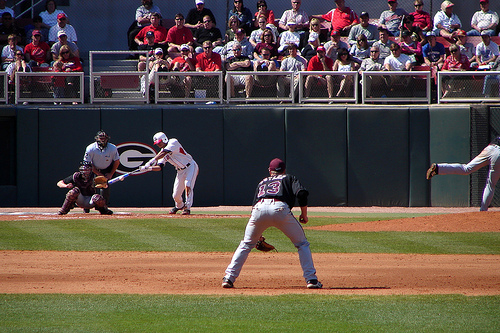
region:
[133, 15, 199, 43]
men wearing red shirts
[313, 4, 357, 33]
man wearing red shirt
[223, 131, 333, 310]
pitcher wearing baseball uniform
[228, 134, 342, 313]
pitcher wearing gray, blue and red baseball uniform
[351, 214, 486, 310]
green and brown baseball field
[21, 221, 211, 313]
green and brown baseball field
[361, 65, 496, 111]
white fence at baseball stadium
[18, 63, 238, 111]
white fence at baseball stadium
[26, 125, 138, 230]
umpire and catcher at baseball game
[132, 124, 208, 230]
batter with red and white uniform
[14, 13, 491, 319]
baseball game is underway.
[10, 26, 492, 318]
baseball game taking place in daytime.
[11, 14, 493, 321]
baseball game with much action.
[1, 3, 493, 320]
baseball game with great action.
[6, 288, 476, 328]
patch of green grass on ball field.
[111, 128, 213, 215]
baseball player swinging bat.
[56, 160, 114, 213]
baseball player squatting in position.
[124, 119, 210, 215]
baseball player in white uniform.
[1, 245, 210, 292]
patch of brown dirt on ball field.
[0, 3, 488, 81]
spectators at ball game.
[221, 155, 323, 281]
the baseball player is bent over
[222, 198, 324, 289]
the player's pant are whire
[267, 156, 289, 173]
the baseball player is wearing a cap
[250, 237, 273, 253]
the player has a baseball glove on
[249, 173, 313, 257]
the player's arms are down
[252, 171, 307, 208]
the player is wearing a dark shirt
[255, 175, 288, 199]
the shirt has lettering on it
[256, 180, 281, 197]
the shirt has number's on it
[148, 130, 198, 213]
the player is wearing a white uniform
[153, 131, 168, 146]
the player is wearing a helmet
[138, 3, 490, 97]
a crowd in the staduim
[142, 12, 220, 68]
four people wearing red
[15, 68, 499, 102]
seven guard rails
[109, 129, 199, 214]
a baseball player hitting a ball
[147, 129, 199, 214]
a baseball player in a white and red uniform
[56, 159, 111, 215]
a catcher trying to catch a ball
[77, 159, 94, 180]
a catcher's helmet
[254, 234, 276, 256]
a baseball mitt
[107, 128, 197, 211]
a player swinging a bat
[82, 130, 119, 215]
an umpire watching the ball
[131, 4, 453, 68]
these are spectectors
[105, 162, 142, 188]
this is a a base ball bat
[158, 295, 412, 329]
this is a grass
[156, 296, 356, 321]
the grass is green in color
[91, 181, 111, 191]
this is abase ball gloves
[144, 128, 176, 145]
this is a helmet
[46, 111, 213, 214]
these are base ball players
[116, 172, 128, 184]
this is a ball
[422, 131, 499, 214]
the man is felling down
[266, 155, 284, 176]
this is acap